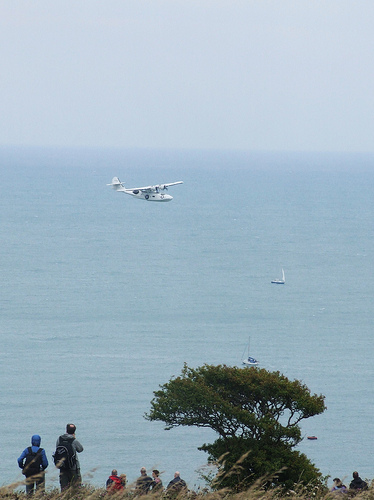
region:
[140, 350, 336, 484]
small tree on a cliff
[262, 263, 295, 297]
sailboat is in the water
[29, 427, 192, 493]
onlookers are watching the plane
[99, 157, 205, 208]
small plane in the air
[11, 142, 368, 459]
cliff overlookig the ocean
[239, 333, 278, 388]
sailboat in the ocean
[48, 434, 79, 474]
man wearing black backpack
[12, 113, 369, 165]
sky is hazy and blue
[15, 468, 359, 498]
tall brown dried grass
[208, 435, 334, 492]
small bush next to tree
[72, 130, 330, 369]
airplanes in the background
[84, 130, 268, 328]
airplanes in the sky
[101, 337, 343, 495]
trees near the ocean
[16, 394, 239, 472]
people admiring the view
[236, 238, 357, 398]
sailboats on the ocean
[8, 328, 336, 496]
lots of weed near the people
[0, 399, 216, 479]
balding man staring at the sky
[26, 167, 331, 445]
blue ocean and sky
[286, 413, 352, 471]
a very small boat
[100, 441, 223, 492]
people sitting down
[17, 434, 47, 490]
a person standing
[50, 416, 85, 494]
a person standing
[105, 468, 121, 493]
a person standing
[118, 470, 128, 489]
a person standing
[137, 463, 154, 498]
a person standing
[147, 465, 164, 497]
a person standing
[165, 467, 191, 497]
a person standing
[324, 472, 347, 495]
a person standing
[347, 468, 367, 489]
a person standing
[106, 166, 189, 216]
a plane in the sky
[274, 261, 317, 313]
boat on the water.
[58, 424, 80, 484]
person with grey shirt.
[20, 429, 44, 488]
person with blue shirt.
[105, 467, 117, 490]
person with red shirt.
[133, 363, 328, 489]
green tree on ground.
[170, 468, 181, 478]
person with bald head.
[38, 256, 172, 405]
body of blue water.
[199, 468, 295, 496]
pieces of brown grass.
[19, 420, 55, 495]
person wearing a hoodie.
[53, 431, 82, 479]
backpack on persons back.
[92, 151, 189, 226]
Plane in the sky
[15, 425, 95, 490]
People looking at water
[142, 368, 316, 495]
The tree is green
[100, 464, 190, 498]
People down the hill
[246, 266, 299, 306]
Boat in the water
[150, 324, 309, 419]
The water is calm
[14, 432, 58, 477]
Person wearing a blue hoodie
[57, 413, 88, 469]
This person is bald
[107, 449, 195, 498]
Five people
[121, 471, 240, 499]
Brown grass in the front